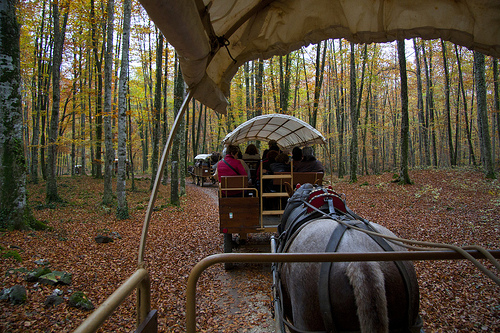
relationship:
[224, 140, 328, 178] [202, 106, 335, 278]
people in wagon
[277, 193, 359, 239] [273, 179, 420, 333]
harness on zebra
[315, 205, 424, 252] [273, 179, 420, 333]
rein of zebra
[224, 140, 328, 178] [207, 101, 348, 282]
people in cart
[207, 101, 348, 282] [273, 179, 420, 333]
cart by zebra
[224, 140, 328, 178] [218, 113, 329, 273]
people in cart